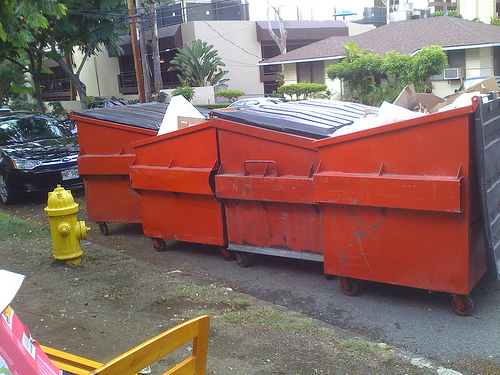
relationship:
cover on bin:
[212, 86, 376, 138] [209, 106, 331, 270]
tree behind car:
[1, 0, 138, 111] [2, 109, 90, 209]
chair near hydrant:
[30, 310, 237, 374] [43, 183, 94, 273]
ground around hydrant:
[22, 265, 171, 365] [20, 166, 108, 273]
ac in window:
[443, 67, 463, 80] [431, 49, 465, 79]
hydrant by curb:
[41, 182, 96, 269] [5, 206, 460, 373]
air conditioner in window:
[442, 65, 462, 80] [439, 48, 470, 78]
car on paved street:
[2, 109, 90, 209] [0, 196, 500, 374]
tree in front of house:
[329, 39, 440, 105] [266, 7, 497, 102]